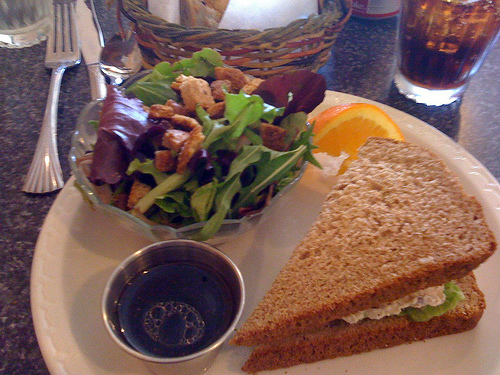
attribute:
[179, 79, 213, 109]
crouton — crispy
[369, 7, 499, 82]
glass — filled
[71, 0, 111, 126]
knife — silver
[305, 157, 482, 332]
bread — wheat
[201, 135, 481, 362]
sandwich — half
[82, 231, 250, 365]
cup — stainless steel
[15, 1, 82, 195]
fork — silver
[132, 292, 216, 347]
bubbles — dark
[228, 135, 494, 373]
sandwich — cut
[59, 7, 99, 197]
knife — silver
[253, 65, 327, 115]
leaf — green, purple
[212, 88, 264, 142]
leaf — green, purple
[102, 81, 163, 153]
leaf — green, purple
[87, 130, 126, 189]
leaf — green, purple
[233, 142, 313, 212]
leaf — green, purple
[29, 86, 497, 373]
plate — white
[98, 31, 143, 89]
spoon — silver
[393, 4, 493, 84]
beverage — dark colored